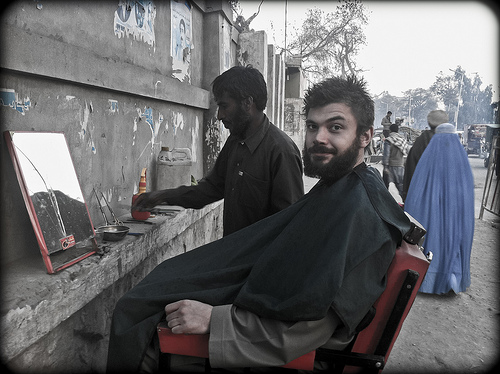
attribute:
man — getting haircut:
[105, 73, 411, 373]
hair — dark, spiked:
[298, 75, 375, 154]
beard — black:
[301, 135, 360, 181]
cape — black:
[103, 164, 411, 374]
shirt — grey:
[208, 303, 359, 369]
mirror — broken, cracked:
[3, 131, 100, 275]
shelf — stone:
[0, 197, 224, 367]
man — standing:
[131, 63, 306, 238]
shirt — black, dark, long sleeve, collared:
[170, 112, 305, 238]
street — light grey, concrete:
[302, 153, 499, 373]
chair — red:
[158, 211, 433, 374]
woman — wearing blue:
[404, 123, 475, 296]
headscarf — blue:
[404, 123, 474, 298]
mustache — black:
[308, 146, 337, 154]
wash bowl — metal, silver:
[98, 227, 131, 241]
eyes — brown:
[306, 123, 342, 131]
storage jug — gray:
[156, 146, 194, 191]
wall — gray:
[0, 0, 203, 266]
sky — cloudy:
[232, 2, 499, 111]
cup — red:
[132, 193, 151, 221]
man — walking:
[403, 110, 449, 202]